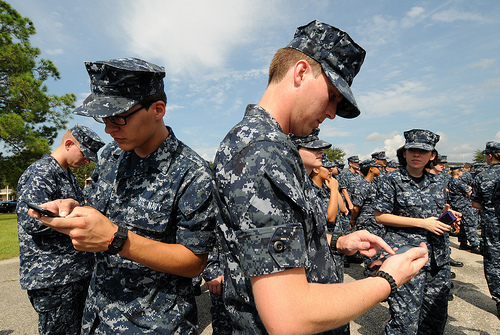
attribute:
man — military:
[66, 59, 220, 331]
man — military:
[207, 17, 384, 334]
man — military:
[16, 116, 101, 319]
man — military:
[475, 141, 498, 273]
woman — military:
[356, 119, 457, 330]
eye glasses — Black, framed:
[92, 94, 169, 129]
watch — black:
[94, 217, 158, 287]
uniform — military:
[14, 154, 99, 334]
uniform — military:
[76, 125, 219, 333]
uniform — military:
[209, 100, 351, 334]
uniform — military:
[372, 163, 455, 333]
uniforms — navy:
[180, 102, 348, 333]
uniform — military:
[225, 80, 347, 263]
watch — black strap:
[96, 221, 129, 262]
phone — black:
[385, 242, 420, 264]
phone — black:
[434, 209, 454, 229]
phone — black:
[25, 200, 59, 218]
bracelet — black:
[364, 268, 396, 302]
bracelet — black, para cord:
[368, 270, 395, 302]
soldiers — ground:
[215, 11, 402, 331]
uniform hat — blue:
[319, 19, 379, 105]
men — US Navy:
[16, 20, 499, 332]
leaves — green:
[0, 0, 75, 182]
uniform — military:
[146, 19, 359, 296]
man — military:
[185, 17, 362, 325]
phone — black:
[438, 209, 455, 226]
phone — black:
[381, 243, 421, 259]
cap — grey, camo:
[56, 36, 224, 144]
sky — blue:
[1, 0, 499, 163]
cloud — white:
[407, 5, 423, 15]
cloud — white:
[476, 55, 499, 71]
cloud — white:
[353, 80, 452, 112]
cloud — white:
[116, 3, 277, 73]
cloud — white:
[209, 91, 229, 101]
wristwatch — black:
[110, 220, 136, 262]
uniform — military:
[209, 20, 361, 332]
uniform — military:
[372, 129, 463, 333]